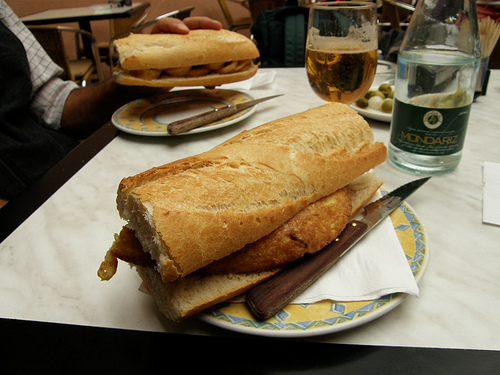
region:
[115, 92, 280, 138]
a plate with a knife on it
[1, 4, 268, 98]
a man holding a sandwich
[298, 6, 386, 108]
a glass of white wine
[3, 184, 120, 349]
white paper covering the table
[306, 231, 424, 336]
a white napkin on the plate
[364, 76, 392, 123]
a plate with assorted olives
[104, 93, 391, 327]
a sandwich on a plate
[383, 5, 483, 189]
a bottle of water on the table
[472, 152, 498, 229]
a white napkin on the table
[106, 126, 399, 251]
crusty bread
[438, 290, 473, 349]
part of a table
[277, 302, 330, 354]
edge of a plate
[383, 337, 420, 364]
edge of a plate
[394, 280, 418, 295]
edge of a saviet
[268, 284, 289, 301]
edge of a handle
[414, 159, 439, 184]
tip of a knife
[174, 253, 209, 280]
edge of a bread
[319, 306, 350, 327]
part of a plate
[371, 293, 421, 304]
edge of a tissue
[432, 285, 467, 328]
part of a paper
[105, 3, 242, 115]
person holding a sandwhich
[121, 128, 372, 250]
sandwhich on a plate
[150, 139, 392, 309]
sandwhich sitting on a plate with a knife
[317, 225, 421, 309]
white liner on a plate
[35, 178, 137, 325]
white paper cover on table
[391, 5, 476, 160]
bottle of clear beverage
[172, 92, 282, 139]
knife with wooden handle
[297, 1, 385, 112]
glass with amber beverage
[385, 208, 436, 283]
plate with yellow and blue design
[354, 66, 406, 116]
plate filled with olives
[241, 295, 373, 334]
the plate is yellow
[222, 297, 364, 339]
the plate has blue designs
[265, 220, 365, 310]
the knife handle is wood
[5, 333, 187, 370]
the table is black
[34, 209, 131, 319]
the sheet is white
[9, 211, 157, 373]
the cloth is on table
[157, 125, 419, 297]
knife beside the sandwhich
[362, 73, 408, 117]
olives on the plate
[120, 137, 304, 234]
the bread is crusty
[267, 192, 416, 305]
napkin under the knife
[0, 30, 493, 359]
Food is on the table.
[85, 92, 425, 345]
A sandwich is on the plate.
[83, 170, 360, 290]
A piece of meat is in the sandwich.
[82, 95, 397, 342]
The sandwich is large.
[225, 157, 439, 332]
A knife is on the plate.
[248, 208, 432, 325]
A napkin is on the plate.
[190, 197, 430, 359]
The plate is yellow and blue.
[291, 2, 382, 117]
A glass of wine is next to the plate.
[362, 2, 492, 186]
A bottle is next to the plate.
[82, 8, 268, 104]
A person holds the sandwich.